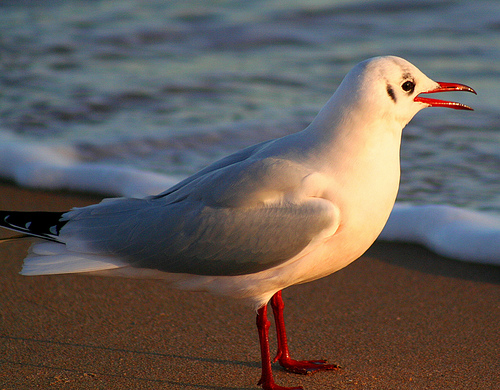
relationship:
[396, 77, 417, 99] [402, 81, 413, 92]
ring around eye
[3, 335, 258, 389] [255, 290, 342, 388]
shadow of legs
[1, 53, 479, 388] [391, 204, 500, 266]
bird above seafoam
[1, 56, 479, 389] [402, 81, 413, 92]
bird has eye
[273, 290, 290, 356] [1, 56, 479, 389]
leg of bird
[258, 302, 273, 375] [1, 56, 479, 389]
leg of bird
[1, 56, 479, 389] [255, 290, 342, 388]
bird has legs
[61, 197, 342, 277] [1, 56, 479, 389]
wing of bird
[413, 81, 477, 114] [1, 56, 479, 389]
beak of bird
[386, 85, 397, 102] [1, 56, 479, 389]
spot on bird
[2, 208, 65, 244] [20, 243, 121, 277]
feathers on tail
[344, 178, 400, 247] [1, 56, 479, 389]
chest on bird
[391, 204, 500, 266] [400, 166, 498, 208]
seafoam on wave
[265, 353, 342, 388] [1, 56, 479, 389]
feet on bird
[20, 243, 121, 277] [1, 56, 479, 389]
tail on bird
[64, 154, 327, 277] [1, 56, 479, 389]
wings on bird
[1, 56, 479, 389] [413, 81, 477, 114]
bird has beak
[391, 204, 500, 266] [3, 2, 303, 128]
seafoam on water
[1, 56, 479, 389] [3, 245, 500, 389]
bird on beach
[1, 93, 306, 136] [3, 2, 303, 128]
waves in water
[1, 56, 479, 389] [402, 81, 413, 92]
bird with eye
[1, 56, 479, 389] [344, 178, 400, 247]
bird with chest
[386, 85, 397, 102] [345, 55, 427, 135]
spot on head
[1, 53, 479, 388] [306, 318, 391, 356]
bird on sand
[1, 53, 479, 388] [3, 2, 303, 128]
bird by water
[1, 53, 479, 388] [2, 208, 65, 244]
bird with feathers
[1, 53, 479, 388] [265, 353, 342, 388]
bird with feet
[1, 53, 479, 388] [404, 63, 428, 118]
bird has face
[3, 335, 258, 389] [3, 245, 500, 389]
shadow on beach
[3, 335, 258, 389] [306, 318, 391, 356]
shadow on sand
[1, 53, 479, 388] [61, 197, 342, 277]
bird with wing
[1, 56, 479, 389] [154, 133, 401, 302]
bird with body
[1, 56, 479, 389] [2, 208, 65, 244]
bird has feathers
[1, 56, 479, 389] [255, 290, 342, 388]
bird with legs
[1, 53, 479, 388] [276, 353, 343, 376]
bird has foot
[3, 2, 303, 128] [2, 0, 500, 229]
water in ocean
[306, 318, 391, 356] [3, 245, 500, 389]
sand on beach